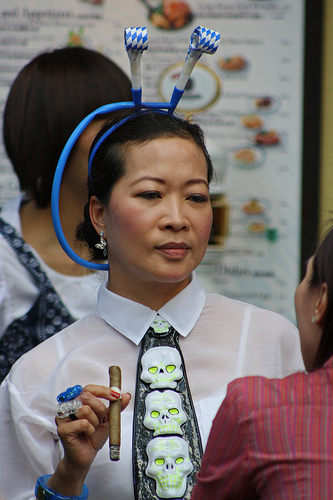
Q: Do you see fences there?
A: No, there are no fences.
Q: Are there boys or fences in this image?
A: No, there are no fences or boys.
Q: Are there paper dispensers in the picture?
A: No, there are no paper dispensers.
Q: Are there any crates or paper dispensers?
A: No, there are no paper dispensers or crates.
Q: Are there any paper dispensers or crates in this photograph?
A: No, there are no paper dispensers or crates.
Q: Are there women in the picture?
A: Yes, there is a woman.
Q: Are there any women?
A: Yes, there is a woman.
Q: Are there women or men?
A: Yes, there is a woman.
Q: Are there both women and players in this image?
A: No, there is a woman but no players.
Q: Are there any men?
A: No, there are no men.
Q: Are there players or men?
A: No, there are no men or players.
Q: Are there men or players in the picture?
A: No, there are no men or players.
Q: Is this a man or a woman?
A: This is a woman.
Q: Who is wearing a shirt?
A: The woman is wearing a shirt.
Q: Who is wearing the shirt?
A: The woman is wearing a shirt.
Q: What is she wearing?
A: The woman is wearing a shirt.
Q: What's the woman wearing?
A: The woman is wearing a shirt.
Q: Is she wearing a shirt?
A: Yes, the woman is wearing a shirt.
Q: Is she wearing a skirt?
A: No, the woman is wearing a shirt.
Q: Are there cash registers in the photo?
A: No, there are no cash registers.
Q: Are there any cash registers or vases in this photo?
A: No, there are no cash registers or vases.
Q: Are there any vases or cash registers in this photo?
A: No, there are no cash registers or vases.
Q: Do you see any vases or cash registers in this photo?
A: No, there are no cash registers or vases.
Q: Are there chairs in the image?
A: No, there are no chairs.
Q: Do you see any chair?
A: No, there are no chairs.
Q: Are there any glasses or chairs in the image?
A: No, there are no chairs or glasses.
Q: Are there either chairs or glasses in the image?
A: No, there are no chairs or glasses.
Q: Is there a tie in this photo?
A: Yes, there is a tie.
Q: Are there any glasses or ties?
A: Yes, there is a tie.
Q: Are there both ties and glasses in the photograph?
A: No, there is a tie but no glasses.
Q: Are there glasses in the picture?
A: No, there are no glasses.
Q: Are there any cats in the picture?
A: No, there are no cats.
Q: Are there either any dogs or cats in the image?
A: No, there are no cats or dogs.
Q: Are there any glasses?
A: No, there are no glasses.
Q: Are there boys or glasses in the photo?
A: No, there are no glasses or boys.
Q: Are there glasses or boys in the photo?
A: No, there are no glasses or boys.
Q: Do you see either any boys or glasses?
A: No, there are no glasses or boys.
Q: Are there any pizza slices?
A: No, there are no pizza slices.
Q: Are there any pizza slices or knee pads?
A: No, there are no pizza slices or knee pads.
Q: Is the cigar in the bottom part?
A: Yes, the cigar is in the bottom of the image.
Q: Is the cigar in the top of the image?
A: No, the cigar is in the bottom of the image.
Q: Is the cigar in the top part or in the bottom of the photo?
A: The cigar is in the bottom of the image.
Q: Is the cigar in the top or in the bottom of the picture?
A: The cigar is in the bottom of the image.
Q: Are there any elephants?
A: No, there are no elephants.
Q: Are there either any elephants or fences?
A: No, there are no elephants or fences.